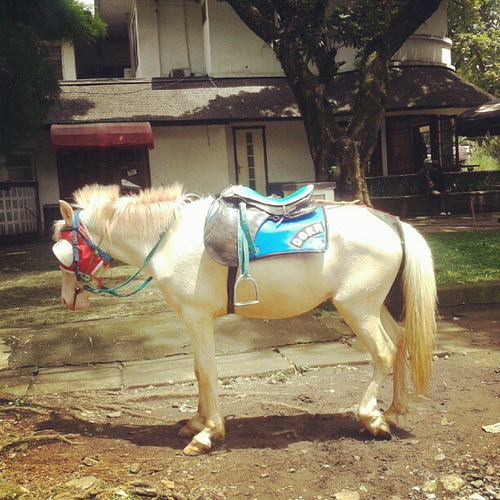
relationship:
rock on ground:
[449, 460, 487, 489] [220, 442, 441, 495]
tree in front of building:
[230, 8, 410, 225] [12, 7, 461, 222]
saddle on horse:
[202, 175, 332, 266] [40, 177, 462, 440]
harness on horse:
[68, 195, 188, 301] [52, 180, 439, 457]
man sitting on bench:
[416, 156, 444, 217] [366, 171, 497, 221]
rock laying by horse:
[128, 457, 142, 472] [52, 180, 439, 457]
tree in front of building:
[230, 8, 410, 225] [0, 0, 500, 245]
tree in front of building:
[3, 1, 107, 159] [0, 0, 500, 245]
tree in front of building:
[446, 0, 498, 101] [0, 0, 500, 245]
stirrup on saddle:
[232, 272, 259, 307] [202, 175, 332, 266]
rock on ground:
[420, 478, 438, 497] [5, 236, 497, 498]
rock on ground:
[434, 460, 486, 497] [424, 479, 459, 496]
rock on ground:
[441, 474, 462, 493] [5, 236, 497, 498]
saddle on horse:
[202, 175, 332, 266] [52, 180, 439, 457]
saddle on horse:
[202, 175, 332, 266] [41, 165, 449, 449]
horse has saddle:
[41, 165, 449, 449] [200, 169, 336, 309]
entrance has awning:
[58, 149, 149, 187] [47, 120, 153, 149]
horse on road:
[41, 165, 449, 449] [77, 367, 461, 490]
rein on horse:
[72, 211, 179, 291] [52, 180, 439, 457]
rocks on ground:
[396, 450, 486, 499] [403, 105, 449, 141]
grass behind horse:
[429, 224, 498, 282] [52, 180, 439, 457]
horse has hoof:
[52, 180, 439, 457] [179, 423, 199, 438]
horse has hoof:
[52, 180, 439, 457] [179, 435, 210, 457]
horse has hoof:
[52, 180, 439, 457] [367, 417, 392, 440]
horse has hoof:
[52, 180, 439, 457] [381, 412, 397, 429]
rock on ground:
[465, 461, 483, 497] [51, 355, 143, 440]